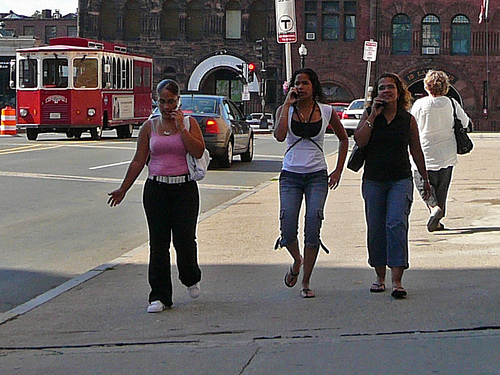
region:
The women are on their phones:
[117, 61, 414, 356]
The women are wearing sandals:
[267, 236, 454, 353]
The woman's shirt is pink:
[130, 122, 216, 209]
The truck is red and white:
[4, 28, 158, 153]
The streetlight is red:
[222, 51, 273, 83]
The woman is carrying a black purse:
[444, 91, 492, 173]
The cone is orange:
[0, 103, 54, 163]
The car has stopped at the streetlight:
[151, 73, 268, 170]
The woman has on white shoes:
[129, 235, 233, 345]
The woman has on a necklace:
[154, 121, 189, 151]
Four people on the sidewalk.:
[92, 45, 498, 294]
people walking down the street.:
[90, 40, 483, 327]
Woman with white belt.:
[67, 72, 252, 334]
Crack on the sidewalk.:
[193, 327, 320, 364]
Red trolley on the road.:
[13, 32, 154, 138]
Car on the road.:
[18, 85, 308, 277]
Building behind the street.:
[75, 7, 472, 199]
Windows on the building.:
[308, 10, 463, 58]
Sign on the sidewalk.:
[258, 2, 328, 112]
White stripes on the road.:
[48, 166, 115, 216]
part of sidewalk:
[252, 312, 462, 373]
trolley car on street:
[7, 42, 132, 134]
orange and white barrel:
[2, 101, 12, 135]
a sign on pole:
[362, 39, 382, 66]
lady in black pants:
[95, 76, 215, 306]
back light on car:
[203, 108, 233, 138]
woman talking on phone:
[270, 70, 346, 298]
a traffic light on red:
[238, 55, 255, 86]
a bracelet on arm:
[362, 117, 379, 132]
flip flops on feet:
[370, 278, 414, 300]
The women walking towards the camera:
[95, 66, 430, 317]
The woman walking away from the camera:
[406, 66, 474, 236]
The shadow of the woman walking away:
[438, 220, 499, 238]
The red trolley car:
[8, 33, 153, 144]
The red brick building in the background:
[73, 0, 498, 130]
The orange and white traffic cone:
[0, 105, 20, 140]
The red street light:
[245, 62, 256, 70]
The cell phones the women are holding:
[168, 81, 386, 118]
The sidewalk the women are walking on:
[0, 128, 498, 373]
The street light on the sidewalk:
[293, 40, 309, 77]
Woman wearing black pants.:
[151, 188, 215, 273]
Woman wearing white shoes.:
[153, 294, 218, 328]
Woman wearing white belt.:
[140, 174, 225, 204]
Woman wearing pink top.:
[143, 132, 202, 197]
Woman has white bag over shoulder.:
[182, 106, 231, 241]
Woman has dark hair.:
[153, 62, 200, 141]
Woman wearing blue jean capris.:
[269, 185, 350, 296]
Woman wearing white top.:
[284, 97, 328, 199]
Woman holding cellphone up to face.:
[287, 47, 317, 111]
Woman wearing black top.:
[355, 122, 408, 182]